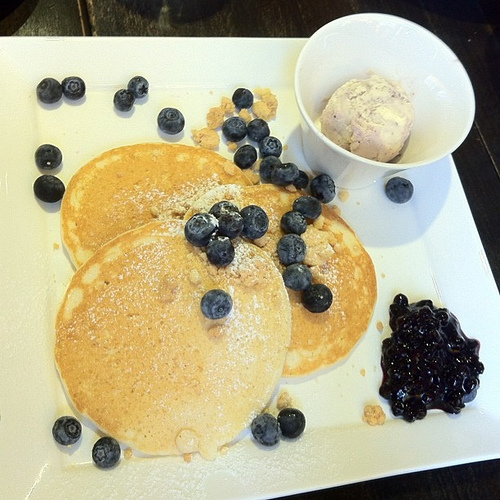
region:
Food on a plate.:
[2, 26, 496, 479]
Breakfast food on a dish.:
[3, 30, 494, 467]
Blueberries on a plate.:
[26, 68, 91, 107]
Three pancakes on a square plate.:
[54, 139, 381, 459]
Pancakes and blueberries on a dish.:
[49, 139, 386, 457]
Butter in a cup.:
[293, 27, 480, 199]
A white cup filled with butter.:
[292, 29, 479, 200]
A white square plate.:
[2, 34, 498, 494]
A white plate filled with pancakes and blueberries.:
[4, 35, 499, 493]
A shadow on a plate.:
[277, 124, 456, 246]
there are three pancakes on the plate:
[53, 138, 378, 455]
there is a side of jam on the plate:
[378, 290, 483, 425]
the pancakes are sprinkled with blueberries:
[24, 73, 369, 458]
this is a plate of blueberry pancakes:
[28, 73, 383, 460]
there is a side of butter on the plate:
[288, 8, 474, 183]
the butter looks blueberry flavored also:
[314, 68, 420, 170]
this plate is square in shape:
[1, 29, 497, 498]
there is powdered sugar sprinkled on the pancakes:
[82, 158, 289, 328]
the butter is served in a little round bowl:
[291, 8, 476, 190]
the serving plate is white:
[6, 30, 498, 495]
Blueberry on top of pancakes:
[199, 185, 275, 259]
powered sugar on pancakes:
[208, 319, 250, 349]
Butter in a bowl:
[333, 75, 419, 149]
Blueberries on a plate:
[59, 423, 116, 462]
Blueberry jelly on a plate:
[403, 310, 475, 399]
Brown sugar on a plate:
[194, 98, 236, 148]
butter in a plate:
[343, 81, 393, 130]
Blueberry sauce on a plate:
[400, 309, 462, 401]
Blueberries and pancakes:
[201, 210, 296, 288]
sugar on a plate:
[179, 438, 269, 471]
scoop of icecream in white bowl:
[315, 65, 426, 162]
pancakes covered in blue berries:
[23, 140, 389, 437]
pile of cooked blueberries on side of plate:
[375, 282, 495, 429]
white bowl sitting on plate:
[250, 17, 497, 245]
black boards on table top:
[1, 0, 284, 32]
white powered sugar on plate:
[146, 458, 303, 499]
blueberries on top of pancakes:
[176, 197, 331, 309]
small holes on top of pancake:
[133, 322, 194, 406]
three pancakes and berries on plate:
[38, 142, 393, 414]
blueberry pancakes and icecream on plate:
[10, 25, 486, 479]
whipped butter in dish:
[341, 76, 408, 146]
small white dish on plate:
[295, 15, 475, 176]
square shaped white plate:
[5, 40, 495, 496]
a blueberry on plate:
[55, 415, 80, 450]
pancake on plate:
[58, 227, 299, 452]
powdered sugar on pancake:
[196, 175, 234, 200]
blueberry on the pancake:
[193, 282, 244, 326]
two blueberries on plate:
[105, 70, 153, 114]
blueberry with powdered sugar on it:
[189, 209, 216, 251]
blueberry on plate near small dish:
[375, 176, 433, 221]